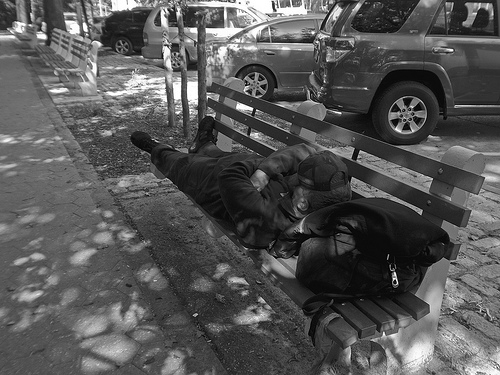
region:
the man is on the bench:
[130, 115, 348, 256]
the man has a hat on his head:
[285, 148, 347, 191]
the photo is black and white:
[8, 0, 495, 372]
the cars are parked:
[100, 15, 495, 133]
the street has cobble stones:
[1, 34, 499, 371]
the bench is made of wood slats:
[133, 85, 483, 342]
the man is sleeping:
[133, 115, 363, 245]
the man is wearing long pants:
[150, 142, 254, 193]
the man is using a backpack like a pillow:
[292, 209, 446, 301]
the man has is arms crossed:
[226, 144, 311, 216]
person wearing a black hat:
[284, 143, 376, 213]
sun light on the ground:
[81, 225, 211, 370]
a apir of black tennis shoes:
[100, 109, 233, 190]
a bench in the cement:
[204, 83, 461, 353]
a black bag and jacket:
[262, 204, 440, 336]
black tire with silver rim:
[340, 87, 440, 167]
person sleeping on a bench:
[61, 153, 446, 318]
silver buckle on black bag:
[349, 258, 421, 308]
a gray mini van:
[250, 0, 493, 150]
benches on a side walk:
[10, 18, 111, 120]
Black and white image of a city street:
[13, 8, 494, 368]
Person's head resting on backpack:
[281, 153, 439, 303]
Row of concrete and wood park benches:
[4, 17, 109, 101]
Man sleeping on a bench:
[129, 116, 467, 363]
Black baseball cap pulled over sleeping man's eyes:
[282, 148, 356, 218]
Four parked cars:
[105, 2, 497, 139]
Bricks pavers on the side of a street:
[335, 140, 498, 367]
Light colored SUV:
[139, 3, 277, 71]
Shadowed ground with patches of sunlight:
[3, 118, 203, 368]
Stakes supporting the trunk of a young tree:
[155, 5, 219, 142]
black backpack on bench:
[317, 187, 443, 320]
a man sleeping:
[127, 111, 353, 249]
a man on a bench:
[127, 105, 359, 256]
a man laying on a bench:
[126, 106, 356, 260]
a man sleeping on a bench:
[129, 77, 489, 373]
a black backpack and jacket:
[271, 194, 453, 324]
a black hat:
[284, 151, 352, 193]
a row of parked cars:
[56, 0, 496, 147]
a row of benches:
[6, 16, 488, 373]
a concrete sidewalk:
[0, 23, 231, 373]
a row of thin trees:
[156, 0, 212, 143]